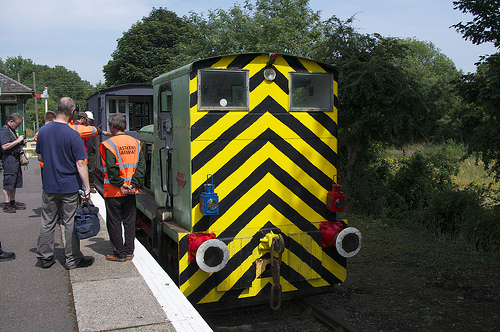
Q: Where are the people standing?
A: Left of train.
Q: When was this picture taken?
A: Daytime.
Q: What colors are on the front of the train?
A: Yellow and black.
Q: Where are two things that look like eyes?
A: Front bottom of train.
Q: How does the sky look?
A: Clear.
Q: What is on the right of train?
A: Trees.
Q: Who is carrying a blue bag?
A: Man in blue shirt.